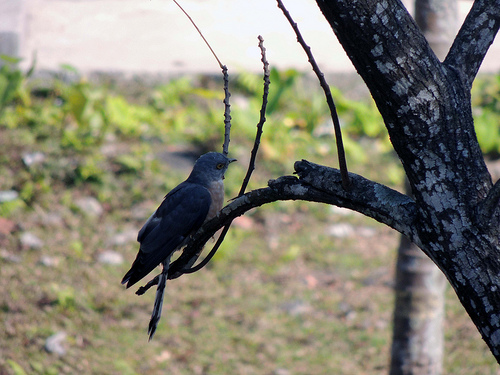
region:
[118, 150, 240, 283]
Blue and grey bird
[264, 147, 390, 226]
Dark leaveless tree branch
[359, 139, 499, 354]
Dark black and grey tree trunk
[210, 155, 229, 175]
Open eye on a blue bird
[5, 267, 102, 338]
Brown soil and grass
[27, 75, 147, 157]
Dark green bushes on the ground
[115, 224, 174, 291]
Dark blue bird's tail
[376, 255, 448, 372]
Brown tree truck on the ground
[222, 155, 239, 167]
Blue bird's sharp beak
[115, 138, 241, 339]
A bird on a tree branch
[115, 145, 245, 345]
A bird on a tree branch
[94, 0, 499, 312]
A black and grey tree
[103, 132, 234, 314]
A dark grey bird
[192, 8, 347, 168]
Twigs on a dead tree limb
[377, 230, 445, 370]
A thin tree trunk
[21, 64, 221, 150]
Green weeds in background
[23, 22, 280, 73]
A building in the far background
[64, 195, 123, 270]
Rocks in the grass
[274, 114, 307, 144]
Yellow leaves in weeds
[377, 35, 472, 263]
Light grey in tree trunk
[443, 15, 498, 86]
A small limb growing off the dark limb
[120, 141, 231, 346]
bird perched on limb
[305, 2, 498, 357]
tree trunk with white splotches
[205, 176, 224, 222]
white chest of the bird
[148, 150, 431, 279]
limb bird is perched on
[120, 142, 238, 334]
blue gray bird with white hcest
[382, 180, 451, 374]
tree trunk in the background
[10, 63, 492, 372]
grass and plants in the background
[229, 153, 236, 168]
beak of the bird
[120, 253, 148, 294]
tail feathers of the bird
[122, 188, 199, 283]
wing of the bird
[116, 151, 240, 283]
bird on the branch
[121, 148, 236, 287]
blue bird on the branch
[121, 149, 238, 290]
blue and white bird on the limb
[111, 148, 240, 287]
small blue and white bird on branch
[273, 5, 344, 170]
branch attached to the tree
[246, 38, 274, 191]
branch attached to tree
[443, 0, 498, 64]
limb attached to tree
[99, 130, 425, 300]
branch holding blue bird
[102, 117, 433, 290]
branch holding blue bird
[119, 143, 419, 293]
branch holding blue and white bird